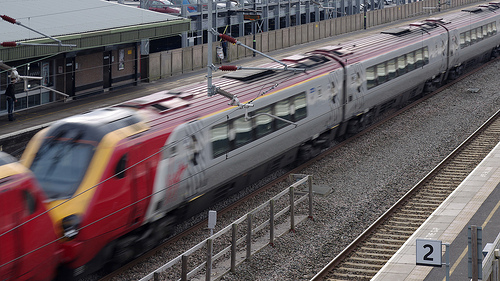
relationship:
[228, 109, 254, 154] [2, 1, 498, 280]
window on train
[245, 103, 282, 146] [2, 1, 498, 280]
window on train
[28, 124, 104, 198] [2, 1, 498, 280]
window on train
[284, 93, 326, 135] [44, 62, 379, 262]
window on a train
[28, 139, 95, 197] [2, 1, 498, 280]
window of train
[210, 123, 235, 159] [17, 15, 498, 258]
windows of a train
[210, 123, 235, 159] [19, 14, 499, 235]
windows of a train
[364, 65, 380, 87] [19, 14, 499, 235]
windows of a train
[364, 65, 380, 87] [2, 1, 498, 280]
windows of a train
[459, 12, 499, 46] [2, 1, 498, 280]
windows of a train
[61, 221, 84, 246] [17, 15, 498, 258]
headlight of a train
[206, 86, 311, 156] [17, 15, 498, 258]
windows on train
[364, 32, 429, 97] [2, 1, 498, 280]
windows on train